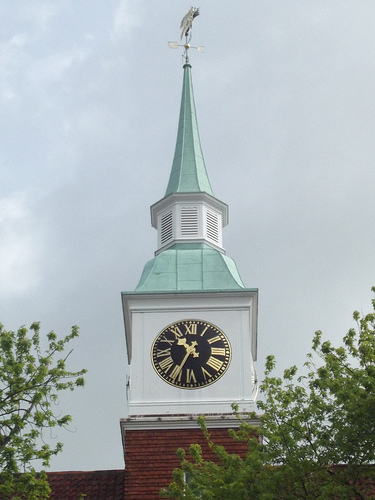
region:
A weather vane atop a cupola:
[153, 2, 239, 79]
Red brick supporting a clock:
[119, 414, 270, 482]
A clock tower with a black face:
[145, 313, 235, 385]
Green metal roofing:
[127, 239, 262, 296]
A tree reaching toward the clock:
[3, 316, 91, 496]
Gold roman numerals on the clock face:
[152, 314, 233, 385]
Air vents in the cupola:
[144, 193, 239, 246]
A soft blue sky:
[227, 20, 361, 147]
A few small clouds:
[24, 12, 136, 90]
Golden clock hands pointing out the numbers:
[171, 335, 201, 364]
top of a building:
[184, 16, 194, 25]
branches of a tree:
[332, 400, 352, 461]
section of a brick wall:
[142, 439, 156, 458]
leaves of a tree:
[308, 433, 316, 445]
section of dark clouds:
[42, 215, 97, 296]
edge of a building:
[122, 416, 140, 428]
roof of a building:
[84, 478, 111, 487]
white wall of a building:
[238, 343, 251, 367]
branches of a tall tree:
[38, 376, 58, 407]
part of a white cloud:
[283, 110, 306, 149]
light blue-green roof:
[103, 4, 271, 380]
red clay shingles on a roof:
[6, 455, 371, 497]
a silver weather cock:
[163, 4, 219, 75]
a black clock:
[140, 317, 233, 399]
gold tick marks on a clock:
[143, 318, 236, 391]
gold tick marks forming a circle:
[142, 316, 251, 398]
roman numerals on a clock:
[144, 309, 235, 391]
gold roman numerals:
[135, 318, 244, 390]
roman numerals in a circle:
[139, 316, 248, 397]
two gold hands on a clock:
[159, 330, 205, 387]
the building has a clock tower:
[2, 1, 373, 499]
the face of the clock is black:
[150, 315, 232, 390]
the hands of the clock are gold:
[148, 318, 233, 391]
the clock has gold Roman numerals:
[151, 317, 231, 389]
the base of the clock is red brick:
[121, 420, 265, 498]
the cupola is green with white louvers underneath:
[145, 62, 231, 252]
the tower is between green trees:
[1, 293, 373, 496]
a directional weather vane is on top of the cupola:
[165, 5, 208, 67]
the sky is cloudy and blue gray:
[10, 5, 374, 381]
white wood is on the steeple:
[127, 299, 259, 415]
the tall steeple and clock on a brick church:
[112, 5, 273, 438]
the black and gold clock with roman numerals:
[146, 319, 234, 395]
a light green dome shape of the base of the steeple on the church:
[116, 243, 272, 303]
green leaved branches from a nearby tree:
[2, 314, 85, 492]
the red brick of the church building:
[124, 433, 160, 498]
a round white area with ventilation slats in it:
[146, 198, 232, 247]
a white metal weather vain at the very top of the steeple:
[163, 10, 214, 64]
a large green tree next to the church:
[260, 352, 374, 498]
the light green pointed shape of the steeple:
[149, 69, 229, 193]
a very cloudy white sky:
[6, 180, 101, 319]